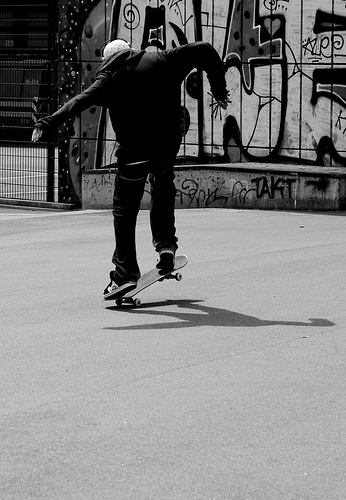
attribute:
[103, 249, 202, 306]
board — slanted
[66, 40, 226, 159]
shirt — black